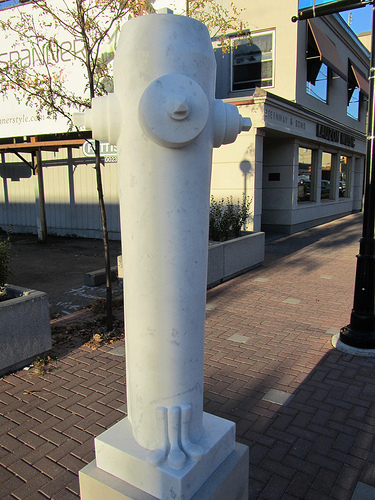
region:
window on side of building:
[292, 152, 311, 197]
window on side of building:
[317, 152, 333, 198]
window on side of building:
[334, 158, 352, 192]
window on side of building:
[304, 63, 329, 102]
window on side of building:
[339, 84, 362, 113]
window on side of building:
[231, 37, 272, 85]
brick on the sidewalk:
[259, 386, 292, 405]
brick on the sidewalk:
[289, 459, 310, 475]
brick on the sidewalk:
[53, 444, 72, 462]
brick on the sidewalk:
[45, 430, 64, 442]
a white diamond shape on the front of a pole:
[173, 95, 192, 113]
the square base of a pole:
[78, 412, 252, 498]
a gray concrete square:
[261, 386, 291, 404]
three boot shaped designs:
[146, 404, 207, 468]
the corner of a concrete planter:
[0, 279, 53, 375]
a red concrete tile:
[38, 427, 65, 444]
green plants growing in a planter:
[210, 193, 251, 241]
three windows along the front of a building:
[297, 146, 350, 202]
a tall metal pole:
[290, 0, 371, 348]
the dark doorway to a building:
[263, 136, 284, 240]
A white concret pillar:
[116, 188, 234, 498]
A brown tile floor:
[232, 347, 299, 401]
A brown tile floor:
[13, 453, 69, 492]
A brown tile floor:
[2, 387, 55, 444]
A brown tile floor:
[52, 383, 106, 423]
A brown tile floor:
[75, 344, 127, 386]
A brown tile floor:
[211, 296, 294, 341]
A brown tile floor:
[259, 267, 342, 310]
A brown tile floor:
[304, 238, 361, 262]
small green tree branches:
[210, 200, 249, 233]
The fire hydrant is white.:
[82, 4, 243, 499]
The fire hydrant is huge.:
[77, 16, 234, 497]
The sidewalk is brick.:
[217, 286, 373, 491]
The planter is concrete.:
[0, 285, 62, 369]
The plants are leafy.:
[209, 191, 247, 241]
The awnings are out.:
[308, 19, 373, 94]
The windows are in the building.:
[296, 144, 353, 209]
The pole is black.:
[340, 100, 373, 355]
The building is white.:
[6, 9, 147, 220]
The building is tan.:
[194, 3, 369, 241]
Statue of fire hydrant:
[68, 6, 259, 497]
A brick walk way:
[4, 206, 368, 498]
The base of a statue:
[68, 415, 259, 498]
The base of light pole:
[332, 180, 373, 366]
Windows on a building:
[289, 18, 332, 106]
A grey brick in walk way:
[264, 388, 291, 406]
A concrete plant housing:
[0, 281, 51, 377]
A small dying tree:
[2, 0, 117, 322]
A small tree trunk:
[90, 143, 115, 329]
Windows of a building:
[295, 140, 353, 203]